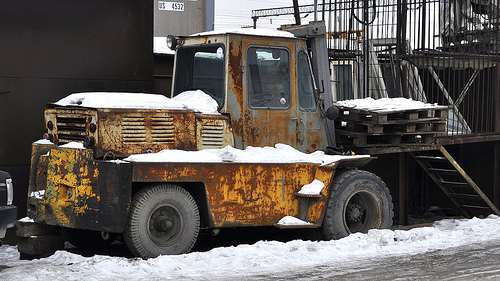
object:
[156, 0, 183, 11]
number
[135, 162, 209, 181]
rust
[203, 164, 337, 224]
rust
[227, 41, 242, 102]
rust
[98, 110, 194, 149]
rust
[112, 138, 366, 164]
snow piles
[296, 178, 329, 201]
step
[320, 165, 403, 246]
tire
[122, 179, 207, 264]
tire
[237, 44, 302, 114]
side window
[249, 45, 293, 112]
window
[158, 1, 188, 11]
white tag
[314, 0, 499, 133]
fence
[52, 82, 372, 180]
snow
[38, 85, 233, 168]
hood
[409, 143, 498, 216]
ladder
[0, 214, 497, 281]
snow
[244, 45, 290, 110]
window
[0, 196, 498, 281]
street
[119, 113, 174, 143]
vent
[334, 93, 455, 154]
pallet pile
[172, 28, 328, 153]
cab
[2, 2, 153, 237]
building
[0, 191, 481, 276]
ground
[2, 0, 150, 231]
wall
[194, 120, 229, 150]
vent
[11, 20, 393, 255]
forklift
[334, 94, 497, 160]
dock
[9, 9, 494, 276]
photo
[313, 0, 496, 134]
bars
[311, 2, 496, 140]
gate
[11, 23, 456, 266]
loader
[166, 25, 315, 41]
roof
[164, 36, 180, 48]
flood light